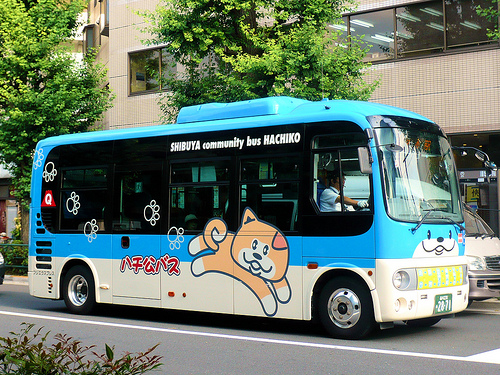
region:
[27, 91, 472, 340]
Blue and white bus driving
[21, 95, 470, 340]
Blue and white bus driving on the street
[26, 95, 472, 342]
Bus with an animal on the side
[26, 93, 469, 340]
Bus with a cartoon animal on the side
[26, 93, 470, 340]
Blue and white bus with a cartoon animal on the side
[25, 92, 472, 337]
Bus with paw marks on the side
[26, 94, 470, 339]
White and blue bus with paw marks on the side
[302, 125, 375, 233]
Man driving a bus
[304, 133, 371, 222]
Man with white gloves driving a bus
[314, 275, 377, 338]
Front wheel of a bus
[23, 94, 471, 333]
a blue and white bus is on the road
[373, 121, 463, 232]
the front windows of the bus has windshield wipers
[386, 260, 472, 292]
headlights are on the front of the bus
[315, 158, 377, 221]
the driver is at the wheel of the bus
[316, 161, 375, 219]
the driver is wearing white gloves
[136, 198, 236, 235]
passengers are on the bus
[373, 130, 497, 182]
rear view mirrors are on the bus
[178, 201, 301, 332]
a kitty is drawn on the side of the bus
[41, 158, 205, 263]
cat footprints are on the side of the bus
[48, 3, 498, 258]
a building is behind the bus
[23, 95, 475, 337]
A shibuya community bus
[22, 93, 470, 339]
A shibuya community bus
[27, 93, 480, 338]
A shibuya community bus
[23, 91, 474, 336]
A shibuya community bus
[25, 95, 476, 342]
A shibuya community bus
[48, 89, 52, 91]
A green leaf on a plant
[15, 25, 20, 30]
A green leaf on a plant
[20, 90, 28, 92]
A green leaf on a plant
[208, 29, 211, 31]
A green leaf on a plant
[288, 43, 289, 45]
A green leaf on a plant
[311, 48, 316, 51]
A green leaf on a plant